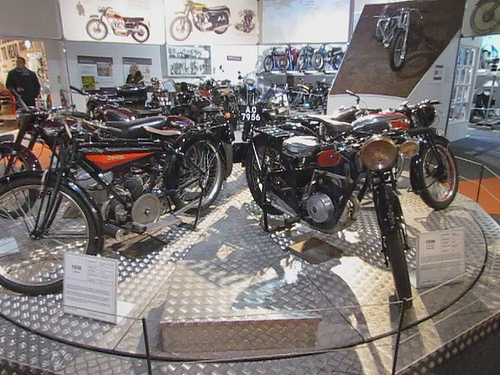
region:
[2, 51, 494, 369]
lots of old bikes on display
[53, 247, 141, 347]
a white sign with black letters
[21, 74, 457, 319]
several red and black bikes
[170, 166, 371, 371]
shadow cast by bike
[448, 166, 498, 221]
yellow stripe on floor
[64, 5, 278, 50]
pictures of motorcycles toward the ceiling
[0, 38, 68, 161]
a man standing in the doorway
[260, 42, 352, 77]
smaller bikes on a wall shelf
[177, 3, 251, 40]
a yellow and black bike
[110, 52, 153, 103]
an old woman looking at sign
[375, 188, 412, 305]
The front wheel is black.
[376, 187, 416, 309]
The front wheel is round.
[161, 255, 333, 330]
The platform is silver.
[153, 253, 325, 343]
The platform is made of metal.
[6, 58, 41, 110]
The man is wearing a scarf.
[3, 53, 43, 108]
The man is wearing a blue scarf.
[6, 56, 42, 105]
The man is wearing a black coat.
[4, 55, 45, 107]
The man's hair is brown.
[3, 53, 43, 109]
The man's hair is short.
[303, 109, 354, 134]
The motorcycle seat is black.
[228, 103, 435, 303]
the motorcycle on display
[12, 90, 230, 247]
the motorcycle on the display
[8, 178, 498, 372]
the display is circular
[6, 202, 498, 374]
the display is metal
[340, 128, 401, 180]
the head light on the motorcycle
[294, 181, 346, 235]
the engine of the motorcycle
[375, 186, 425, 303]
the front wheel of the motorcycle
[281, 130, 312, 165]
the seat of the motorcycle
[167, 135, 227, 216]
the rear wheel of the motorcycle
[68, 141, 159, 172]
the fuel tank of the motorcycle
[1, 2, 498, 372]
a motorcycle and bike store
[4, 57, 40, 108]
a man standing in the motorcycle store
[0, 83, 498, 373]
motorbikes on display in a store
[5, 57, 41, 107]
a man looking at the motorbikes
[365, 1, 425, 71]
a bicycle on display in the store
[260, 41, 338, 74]
bikes on display on a wall shelf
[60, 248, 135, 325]
a white sign on the display of motorbikes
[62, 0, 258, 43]
two motorcycles on wall screen displays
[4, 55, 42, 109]
a man looking to purchase a motorcycle or bicycle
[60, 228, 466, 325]
two white signs with information about the motorcycles and bikes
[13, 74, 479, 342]
bikes on a turntable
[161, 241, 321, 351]
pedestal on a turntable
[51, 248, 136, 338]
sign on a turntable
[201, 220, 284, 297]
shadow casted on turntable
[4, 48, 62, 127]
man in a bike store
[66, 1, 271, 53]
posters of bikes on the wall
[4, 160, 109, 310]
front tire of a bike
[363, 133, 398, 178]
light on a bike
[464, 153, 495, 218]
fence around a turntable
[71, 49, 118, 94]
sign on a wall